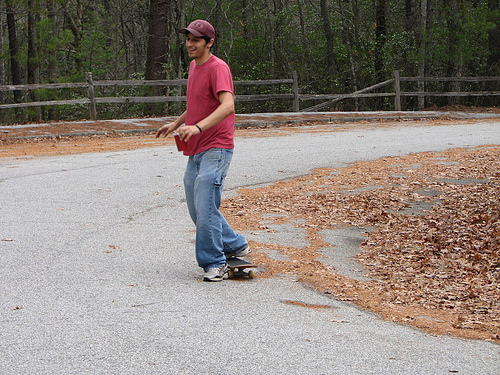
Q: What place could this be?
A: It is a pavement.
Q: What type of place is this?
A: It is a pavement.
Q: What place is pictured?
A: It is a pavement.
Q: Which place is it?
A: It is a pavement.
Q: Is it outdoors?
A: Yes, it is outdoors.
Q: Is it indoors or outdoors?
A: It is outdoors.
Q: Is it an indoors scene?
A: No, it is outdoors.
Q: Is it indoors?
A: No, it is outdoors.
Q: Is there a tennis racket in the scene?
A: No, there are no rackets.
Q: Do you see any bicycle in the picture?
A: No, there are no bicycles.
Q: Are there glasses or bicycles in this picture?
A: No, there are no bicycles or glasses.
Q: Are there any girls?
A: No, there are no girls.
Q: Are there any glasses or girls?
A: No, there are no girls or glasses.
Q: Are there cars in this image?
A: No, there are no cars.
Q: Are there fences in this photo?
A: Yes, there is a fence.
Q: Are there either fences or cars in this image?
A: Yes, there is a fence.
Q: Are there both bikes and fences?
A: No, there is a fence but no bikes.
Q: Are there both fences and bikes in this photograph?
A: No, there is a fence but no bikes.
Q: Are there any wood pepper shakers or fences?
A: Yes, there is a wood fence.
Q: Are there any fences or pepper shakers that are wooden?
A: Yes, the fence is wooden.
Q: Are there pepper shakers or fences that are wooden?
A: Yes, the fence is wooden.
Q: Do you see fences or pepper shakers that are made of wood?
A: Yes, the fence is made of wood.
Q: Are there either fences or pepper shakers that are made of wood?
A: Yes, the fence is made of wood.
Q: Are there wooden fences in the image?
A: Yes, there is a wood fence.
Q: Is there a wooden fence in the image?
A: Yes, there is a wood fence.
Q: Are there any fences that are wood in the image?
A: Yes, there is a wood fence.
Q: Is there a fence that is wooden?
A: Yes, there is a fence that is wooden.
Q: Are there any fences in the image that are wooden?
A: Yes, there is a fence that is wooden.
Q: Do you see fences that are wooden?
A: Yes, there is a fence that is wooden.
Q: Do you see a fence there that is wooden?
A: Yes, there is a fence that is wooden.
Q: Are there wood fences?
A: Yes, there is a fence that is made of wood.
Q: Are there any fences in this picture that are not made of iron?
A: Yes, there is a fence that is made of wood.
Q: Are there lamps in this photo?
A: No, there are no lamps.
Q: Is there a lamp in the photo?
A: No, there are no lamps.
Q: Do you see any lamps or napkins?
A: No, there are no lamps or napkins.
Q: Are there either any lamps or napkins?
A: No, there are no lamps or napkins.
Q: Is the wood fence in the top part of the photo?
A: Yes, the fence is in the top of the image.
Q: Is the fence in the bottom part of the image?
A: No, the fence is in the top of the image.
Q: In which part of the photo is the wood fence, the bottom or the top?
A: The fence is in the top of the image.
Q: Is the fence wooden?
A: Yes, the fence is wooden.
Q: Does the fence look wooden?
A: Yes, the fence is wooden.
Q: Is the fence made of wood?
A: Yes, the fence is made of wood.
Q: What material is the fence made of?
A: The fence is made of wood.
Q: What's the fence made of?
A: The fence is made of wood.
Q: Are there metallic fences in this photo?
A: No, there is a fence but it is wooden.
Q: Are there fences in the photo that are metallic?
A: No, there is a fence but it is wooden.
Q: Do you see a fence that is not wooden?
A: No, there is a fence but it is wooden.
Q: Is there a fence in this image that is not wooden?
A: No, there is a fence but it is wooden.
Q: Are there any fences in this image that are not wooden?
A: No, there is a fence but it is wooden.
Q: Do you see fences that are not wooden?
A: No, there is a fence but it is wooden.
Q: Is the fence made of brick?
A: No, the fence is made of wood.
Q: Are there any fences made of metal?
A: No, there is a fence but it is made of wood.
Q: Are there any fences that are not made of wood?
A: No, there is a fence but it is made of wood.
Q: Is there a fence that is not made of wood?
A: No, there is a fence but it is made of wood.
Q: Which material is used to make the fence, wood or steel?
A: The fence is made of wood.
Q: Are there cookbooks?
A: No, there are no cookbooks.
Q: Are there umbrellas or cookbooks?
A: No, there are no cookbooks or umbrellas.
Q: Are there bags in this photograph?
A: No, there are no bags.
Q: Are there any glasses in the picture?
A: No, there are no glasses.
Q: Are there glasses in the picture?
A: No, there are no glasses.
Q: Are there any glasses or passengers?
A: No, there are no glasses or passengers.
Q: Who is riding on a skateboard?
A: The man is riding on a skateboard.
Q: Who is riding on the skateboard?
A: The man is riding on a skateboard.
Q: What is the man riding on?
A: The man is riding on a skateboard.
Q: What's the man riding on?
A: The man is riding on a skateboard.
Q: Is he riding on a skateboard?
A: Yes, the man is riding on a skateboard.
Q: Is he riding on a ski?
A: No, the man is riding on a skateboard.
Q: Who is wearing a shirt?
A: The man is wearing a shirt.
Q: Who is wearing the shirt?
A: The man is wearing a shirt.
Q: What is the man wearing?
A: The man is wearing a shirt.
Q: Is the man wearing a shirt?
A: Yes, the man is wearing a shirt.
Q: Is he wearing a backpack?
A: No, the man is wearing a shirt.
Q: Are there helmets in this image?
A: No, there are no helmets.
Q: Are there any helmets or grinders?
A: No, there are no helmets or grinders.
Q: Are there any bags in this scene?
A: No, there are no bags.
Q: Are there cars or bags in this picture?
A: No, there are no bags or cars.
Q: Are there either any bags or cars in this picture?
A: No, there are no bags or cars.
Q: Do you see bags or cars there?
A: No, there are no bags or cars.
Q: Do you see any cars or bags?
A: No, there are no bags or cars.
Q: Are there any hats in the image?
A: Yes, there is a hat.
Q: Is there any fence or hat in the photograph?
A: Yes, there is a hat.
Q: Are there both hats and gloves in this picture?
A: No, there is a hat but no gloves.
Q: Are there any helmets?
A: No, there are no helmets.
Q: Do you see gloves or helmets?
A: No, there are no helmets or gloves.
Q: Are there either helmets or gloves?
A: No, there are no helmets or gloves.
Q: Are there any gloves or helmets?
A: No, there are no helmets or gloves.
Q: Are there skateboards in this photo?
A: Yes, there is a skateboard.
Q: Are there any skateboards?
A: Yes, there is a skateboard.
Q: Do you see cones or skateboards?
A: Yes, there is a skateboard.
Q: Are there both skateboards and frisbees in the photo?
A: No, there is a skateboard but no frisbees.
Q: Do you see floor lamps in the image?
A: No, there are no floor lamps.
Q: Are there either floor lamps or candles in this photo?
A: No, there are no floor lamps or candles.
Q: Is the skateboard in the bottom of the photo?
A: Yes, the skateboard is in the bottom of the image.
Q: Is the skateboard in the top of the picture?
A: No, the skateboard is in the bottom of the image.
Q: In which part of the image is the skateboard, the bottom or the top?
A: The skateboard is in the bottom of the image.